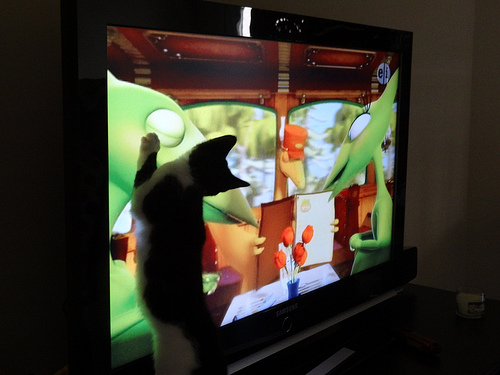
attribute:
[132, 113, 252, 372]
cat — black, white, furry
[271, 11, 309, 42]
remote sensor — black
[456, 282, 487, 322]
container — small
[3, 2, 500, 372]
paint — white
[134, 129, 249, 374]
fur — black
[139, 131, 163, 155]
paw of cat — white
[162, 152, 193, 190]
front neck of cat — white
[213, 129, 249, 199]
ears — pointy, black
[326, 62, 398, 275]
character — green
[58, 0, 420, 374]
tv — flat screen, flatscreen, big, on, shiny, black, a samsung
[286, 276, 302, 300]
vase — blue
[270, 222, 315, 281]
tulips — red